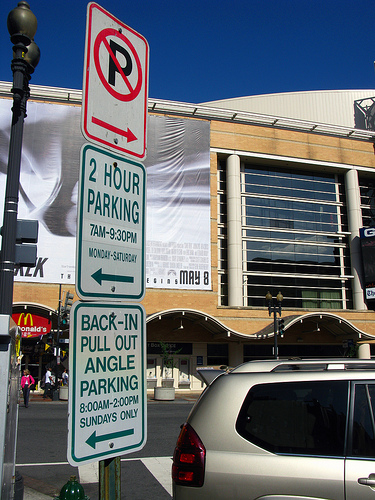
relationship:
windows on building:
[217, 158, 374, 311] [2, 80, 375, 401]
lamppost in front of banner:
[0, 1, 41, 500] [0, 97, 214, 293]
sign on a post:
[81, 1, 150, 161] [97, 455, 121, 500]